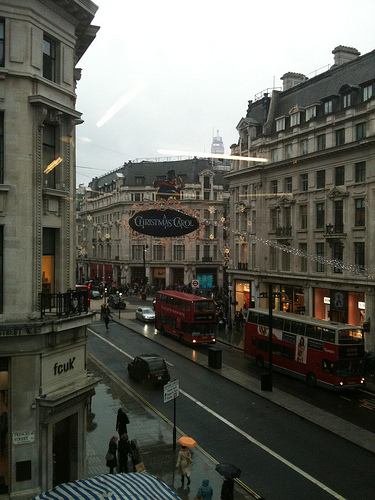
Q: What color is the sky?
A: Grey.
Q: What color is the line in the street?
A: White.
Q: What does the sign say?
A: A Christmas Carol.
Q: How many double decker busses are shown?
A: Two.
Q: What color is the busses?
A: Red.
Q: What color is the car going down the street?
A: Black.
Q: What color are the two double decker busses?
A: Red.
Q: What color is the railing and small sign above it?
A: Black.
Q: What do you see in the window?
A: Glare.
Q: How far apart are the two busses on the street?
A: About ten feet.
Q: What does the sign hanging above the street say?
A: A Christmas Carol.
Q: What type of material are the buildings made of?
A: Stone.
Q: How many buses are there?
A: Two.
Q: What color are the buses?
A: Red.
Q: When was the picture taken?
A: Daytime.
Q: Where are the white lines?
A: Street.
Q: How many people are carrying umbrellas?
A: Two.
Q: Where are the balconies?
A: On the side of the building.